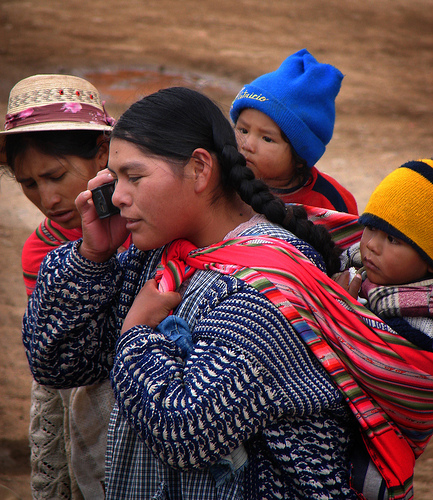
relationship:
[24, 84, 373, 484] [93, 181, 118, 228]
woman on phone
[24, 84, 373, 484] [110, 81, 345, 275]
woman has hair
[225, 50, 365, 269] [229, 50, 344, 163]
boy has hat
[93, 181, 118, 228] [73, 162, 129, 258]
phone in hand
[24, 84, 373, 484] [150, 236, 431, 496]
woman holding fabric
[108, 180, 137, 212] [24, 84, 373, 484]
nose on woman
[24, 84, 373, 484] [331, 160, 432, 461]
woman wearing baby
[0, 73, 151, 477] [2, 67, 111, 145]
woman wearing hat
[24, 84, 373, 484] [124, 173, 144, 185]
person has eye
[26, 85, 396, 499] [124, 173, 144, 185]
person has eye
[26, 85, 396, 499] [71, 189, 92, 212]
person has finger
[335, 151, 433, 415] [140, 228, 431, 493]
toddler in sling